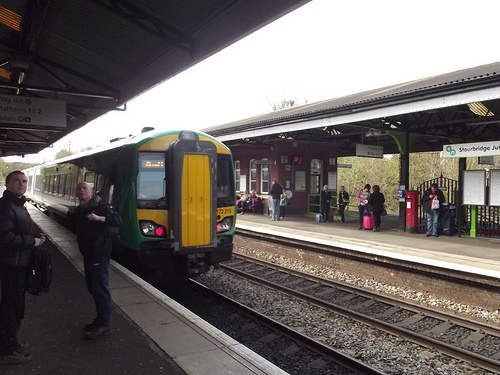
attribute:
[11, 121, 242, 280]
train — electronic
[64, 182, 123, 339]
man — standing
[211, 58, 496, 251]
shelter — overhead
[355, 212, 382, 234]
suitcase — pink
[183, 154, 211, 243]
color — yellow